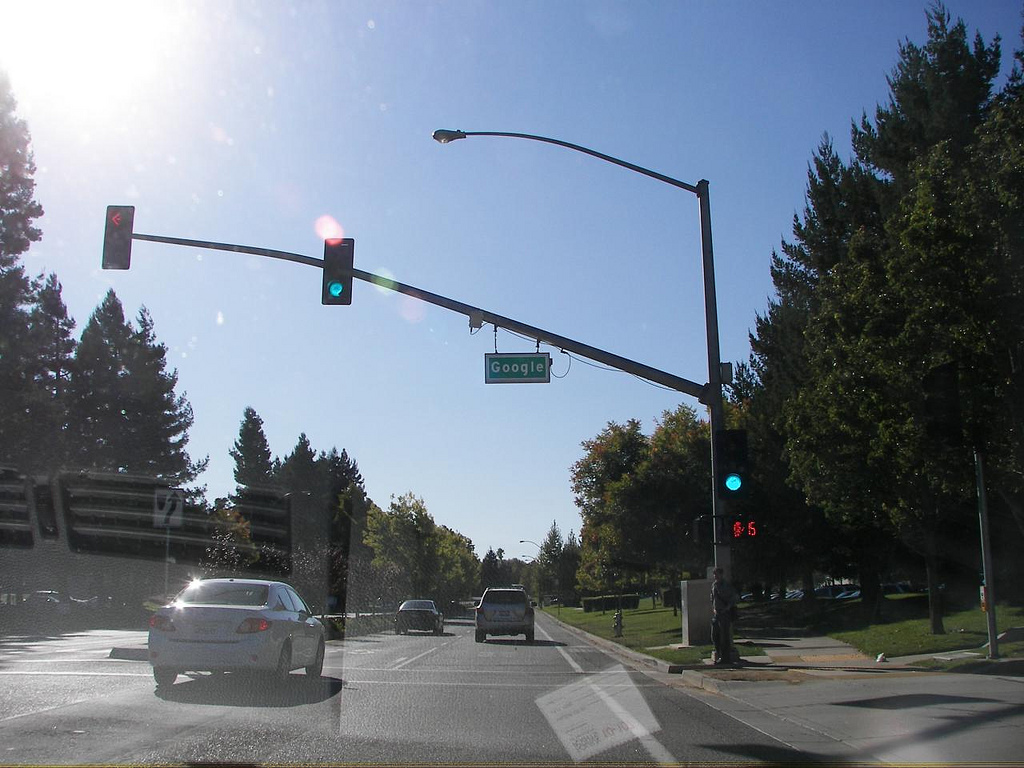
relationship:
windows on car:
[266, 580, 314, 622] [130, 572, 336, 686]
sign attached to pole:
[471, 335, 561, 387] [680, 398, 766, 649]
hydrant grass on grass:
[595, 596, 663, 651] [554, 589, 1012, 696]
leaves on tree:
[814, 235, 901, 325] [804, 83, 1008, 526]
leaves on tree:
[851, 196, 1001, 431] [746, 67, 999, 655]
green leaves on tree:
[841, 284, 928, 379] [754, 22, 1010, 661]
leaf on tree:
[955, 68, 968, 73] [754, 22, 1010, 661]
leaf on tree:
[884, 170, 910, 193] [754, 22, 1010, 661]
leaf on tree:
[933, 151, 954, 180] [754, 22, 1010, 661]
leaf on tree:
[905, 218, 929, 237] [754, 22, 1010, 661]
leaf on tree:
[821, 290, 841, 310] [754, 22, 1010, 661]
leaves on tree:
[900, 146, 992, 235] [915, 206, 1015, 621]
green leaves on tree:
[795, 362, 878, 481] [779, 206, 939, 614]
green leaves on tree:
[628, 493, 667, 533] [593, 399, 714, 584]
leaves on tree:
[597, 431, 737, 565] [574, 403, 771, 598]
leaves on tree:
[980, 129, 1020, 188] [577, 417, 651, 500]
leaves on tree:
[833, 302, 896, 345] [376, 494, 438, 601]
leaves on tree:
[833, 302, 896, 345] [68, 293, 192, 484]